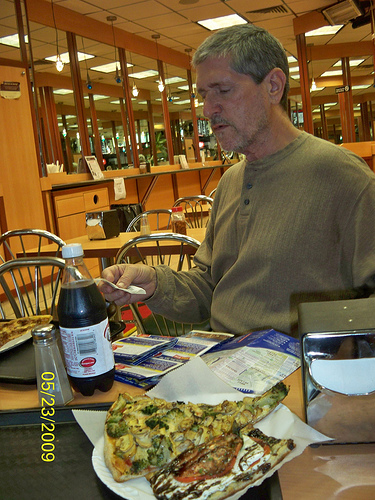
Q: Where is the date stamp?
A: Bottom left corner.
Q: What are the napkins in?
A: Napkin holder.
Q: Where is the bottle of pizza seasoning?
A: On table behind the person.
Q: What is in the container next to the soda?
A: Pepper.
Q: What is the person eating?
A: Pizza.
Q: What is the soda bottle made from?
A: Plastic.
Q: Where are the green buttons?
A: On the green shirt.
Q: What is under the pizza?
A: Paper plate.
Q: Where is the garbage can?
A: By the counter.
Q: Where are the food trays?
A: On the table.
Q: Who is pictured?
A: A man.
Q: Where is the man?
A: In a restaurant.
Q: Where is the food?
A: On the tray.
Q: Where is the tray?
A: On the table.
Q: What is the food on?
A: Plate.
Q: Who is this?
A: Man.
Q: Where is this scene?
A: In a restaurant.